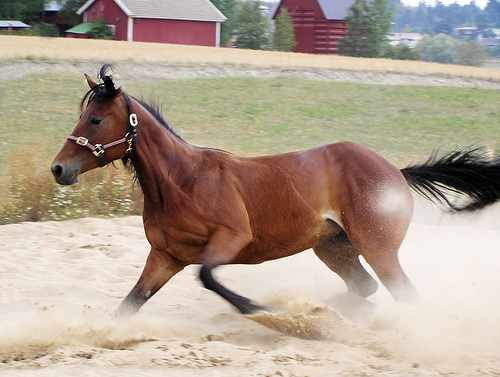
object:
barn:
[268, 0, 379, 56]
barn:
[76, 0, 226, 44]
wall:
[130, 16, 219, 46]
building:
[68, 0, 225, 46]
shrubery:
[234, 10, 284, 41]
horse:
[44, 61, 496, 333]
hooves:
[94, 301, 438, 348]